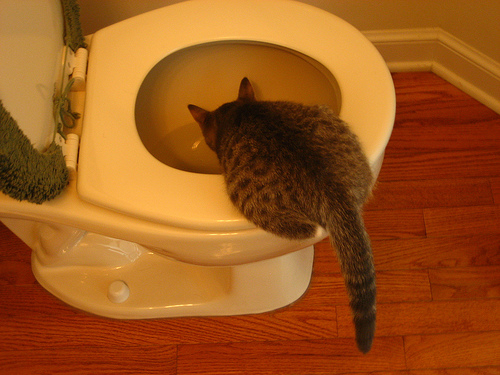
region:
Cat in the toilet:
[165, 73, 371, 220]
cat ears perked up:
[178, 68, 270, 122]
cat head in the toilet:
[172, 68, 265, 136]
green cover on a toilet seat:
[10, 164, 69, 199]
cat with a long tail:
[308, 180, 400, 358]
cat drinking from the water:
[169, 66, 321, 173]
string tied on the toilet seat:
[46, 78, 90, 143]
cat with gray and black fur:
[232, 100, 354, 254]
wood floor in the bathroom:
[384, 218, 495, 374]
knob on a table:
[106, 273, 139, 308]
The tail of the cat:
[333, 215, 376, 349]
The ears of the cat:
[186, 78, 251, 118]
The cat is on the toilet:
[187, 76, 374, 354]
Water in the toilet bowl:
[160, 121, 222, 174]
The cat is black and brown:
[186, 79, 375, 350]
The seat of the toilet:
[78, 0, 398, 233]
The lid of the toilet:
[0, 0, 87, 165]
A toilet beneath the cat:
[1, 0, 398, 315]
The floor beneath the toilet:
[0, 70, 499, 372]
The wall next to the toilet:
[78, 3, 499, 108]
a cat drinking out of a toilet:
[170, 72, 392, 332]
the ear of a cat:
[189, 96, 221, 148]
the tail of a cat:
[315, 209, 395, 345]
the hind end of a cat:
[253, 145, 357, 227]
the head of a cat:
[192, 97, 262, 155]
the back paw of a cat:
[273, 222, 327, 252]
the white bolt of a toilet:
[85, 259, 134, 311]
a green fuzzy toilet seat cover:
[26, 138, 75, 200]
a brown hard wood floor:
[424, 94, 487, 231]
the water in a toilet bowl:
[156, 104, 208, 170]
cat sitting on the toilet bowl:
[177, 73, 403, 359]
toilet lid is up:
[0, 0, 80, 203]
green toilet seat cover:
[0, 0, 71, 205]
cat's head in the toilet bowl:
[179, 78, 293, 155]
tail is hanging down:
[325, 210, 390, 355]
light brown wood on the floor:
[2, 48, 499, 373]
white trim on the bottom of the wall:
[353, 13, 499, 123]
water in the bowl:
[150, 113, 260, 180]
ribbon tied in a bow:
[45, 76, 82, 135]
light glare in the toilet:
[189, 138, 200, 153]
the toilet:
[11, 10, 371, 335]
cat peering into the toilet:
[175, 71, 397, 366]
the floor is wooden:
[345, 85, 495, 365]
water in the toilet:
[151, 115, 203, 165]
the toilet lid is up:
[0, 0, 80, 210]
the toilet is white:
[3, 1, 395, 331]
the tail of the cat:
[320, 205, 399, 363]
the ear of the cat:
[178, 95, 223, 133]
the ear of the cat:
[231, 75, 271, 101]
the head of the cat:
[170, 75, 274, 150]